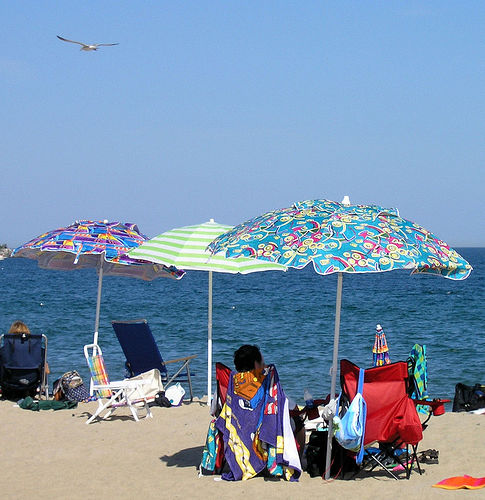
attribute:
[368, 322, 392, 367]
umbrella — closed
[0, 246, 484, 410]
water — blue, placid, choppy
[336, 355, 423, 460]
chair — red 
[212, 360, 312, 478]
chair — beach chair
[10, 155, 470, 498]
beach — red 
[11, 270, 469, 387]
water — blue, calm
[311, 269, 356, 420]
pole — white 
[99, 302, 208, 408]
chair — red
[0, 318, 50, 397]
lady — basking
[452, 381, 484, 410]
bag — black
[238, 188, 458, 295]
umbrella — decorated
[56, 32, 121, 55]
bird — on air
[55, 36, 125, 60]
bird — flying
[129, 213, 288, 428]
umbrella — white , Green 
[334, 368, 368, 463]
purse — blue